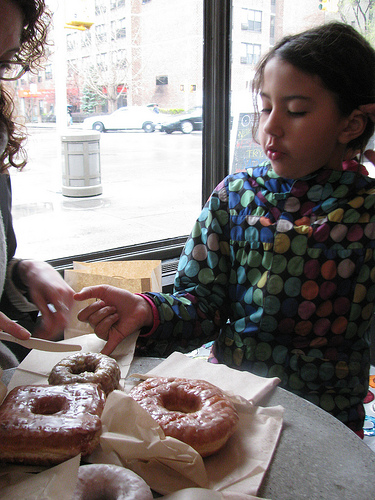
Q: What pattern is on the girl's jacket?
A: Dots.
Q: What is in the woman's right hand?
A: Knife.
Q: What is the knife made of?
A: Plastic.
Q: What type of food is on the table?
A: Donuts.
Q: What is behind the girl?
A: Window.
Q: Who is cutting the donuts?
A: The woman.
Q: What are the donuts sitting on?
A: Napkins.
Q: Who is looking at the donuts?
A: A girl.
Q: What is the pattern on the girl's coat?
A: Colorful circles.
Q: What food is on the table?
A: Donuts.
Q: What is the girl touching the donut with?
A: Her pinkie.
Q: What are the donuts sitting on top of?
A: Napkins.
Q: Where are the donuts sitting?
A: On a table.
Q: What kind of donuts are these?
A: Glazed donuts.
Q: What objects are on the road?
A: Cars.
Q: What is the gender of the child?
A: Female.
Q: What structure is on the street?
A: Building.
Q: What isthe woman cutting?
A: Donut.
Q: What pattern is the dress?
A: Dots.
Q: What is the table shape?
A: Round.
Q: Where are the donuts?
A: Table.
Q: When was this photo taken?
A: During the day.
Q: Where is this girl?
A: At a bakery.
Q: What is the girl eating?
A: Doughnuts.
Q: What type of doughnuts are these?
A: Glazed.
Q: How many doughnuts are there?
A: Four.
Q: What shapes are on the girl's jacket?
A: Circles.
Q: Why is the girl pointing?
A: She is choosing a doughnut.